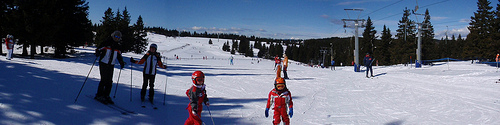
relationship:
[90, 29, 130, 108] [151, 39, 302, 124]
adults on slope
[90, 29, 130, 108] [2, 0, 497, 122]
adults at resort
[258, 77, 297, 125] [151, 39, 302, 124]
child on slope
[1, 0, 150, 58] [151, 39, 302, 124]
trees along slope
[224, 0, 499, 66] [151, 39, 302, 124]
trees along slope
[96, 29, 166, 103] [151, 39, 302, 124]
adults on slope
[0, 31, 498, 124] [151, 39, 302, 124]
snow on slope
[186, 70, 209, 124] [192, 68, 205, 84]
child has helmet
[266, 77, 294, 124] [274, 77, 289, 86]
child has helmet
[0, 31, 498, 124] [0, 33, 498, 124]
snow on ground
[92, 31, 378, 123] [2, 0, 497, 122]
people at resort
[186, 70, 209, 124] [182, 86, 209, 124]
child in snowsuit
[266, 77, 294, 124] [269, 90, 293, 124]
child in snowsuit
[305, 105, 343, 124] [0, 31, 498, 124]
tracks on snow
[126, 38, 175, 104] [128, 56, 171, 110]
parent holding poles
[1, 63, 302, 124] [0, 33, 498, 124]
shadow on ground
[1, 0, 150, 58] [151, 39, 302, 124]
trees on slope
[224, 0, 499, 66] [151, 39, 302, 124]
trees on slope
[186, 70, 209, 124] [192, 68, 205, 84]
child wearing helmet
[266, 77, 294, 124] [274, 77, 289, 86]
child wearing helmet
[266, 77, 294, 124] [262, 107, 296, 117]
child has gloves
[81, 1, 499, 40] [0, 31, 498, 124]
sky over snow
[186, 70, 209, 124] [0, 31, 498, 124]
child in snow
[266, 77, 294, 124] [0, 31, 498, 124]
child in snow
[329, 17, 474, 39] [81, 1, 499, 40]
clouds in sky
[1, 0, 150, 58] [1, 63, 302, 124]
trees have shadow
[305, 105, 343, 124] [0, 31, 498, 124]
tracks in snow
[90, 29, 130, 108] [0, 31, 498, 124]
adults standing in snow